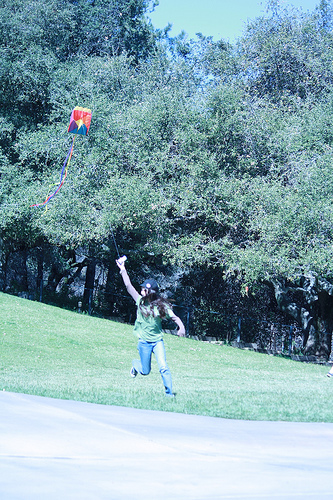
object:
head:
[123, 274, 170, 304]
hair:
[141, 293, 166, 308]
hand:
[110, 245, 133, 272]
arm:
[95, 256, 150, 302]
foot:
[151, 364, 179, 398]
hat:
[145, 272, 167, 297]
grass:
[12, 319, 80, 364]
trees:
[160, 133, 310, 254]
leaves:
[201, 99, 277, 181]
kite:
[59, 82, 97, 166]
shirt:
[133, 306, 169, 343]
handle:
[106, 240, 139, 271]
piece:
[64, 105, 109, 182]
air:
[180, 6, 216, 35]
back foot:
[125, 361, 138, 375]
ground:
[190, 364, 238, 396]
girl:
[122, 273, 182, 394]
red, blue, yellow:
[66, 101, 94, 142]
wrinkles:
[123, 290, 174, 340]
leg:
[149, 348, 179, 390]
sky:
[179, 14, 228, 42]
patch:
[37, 413, 95, 461]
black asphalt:
[88, 427, 163, 473]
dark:
[25, 8, 109, 55]